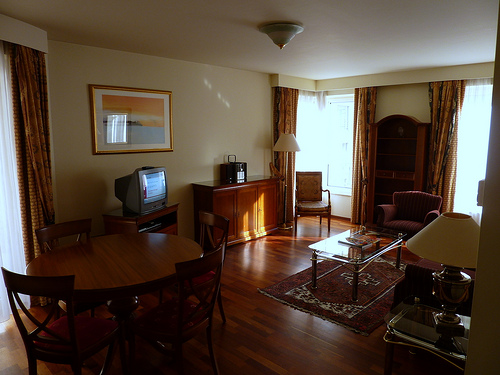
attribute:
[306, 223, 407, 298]
coffee table — glass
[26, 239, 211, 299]
table — wooden, brown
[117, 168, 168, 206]
television — gray, grey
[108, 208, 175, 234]
stand — wood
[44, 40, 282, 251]
wall — white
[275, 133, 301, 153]
lamp shade — white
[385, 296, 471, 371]
end table — glass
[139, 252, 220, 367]
chair by table — red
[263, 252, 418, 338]
carpet — burgundy, red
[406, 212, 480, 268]
lamp shade — white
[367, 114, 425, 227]
book shelf — large